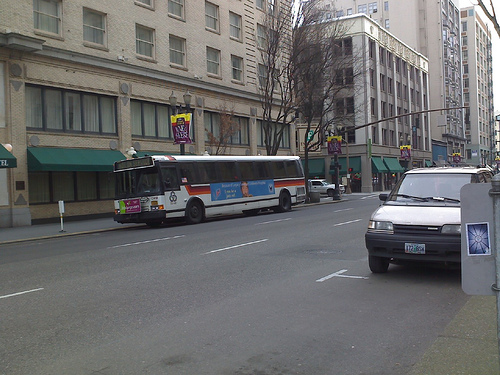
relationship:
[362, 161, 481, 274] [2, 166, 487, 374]
vehicle on road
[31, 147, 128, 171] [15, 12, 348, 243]
awning on building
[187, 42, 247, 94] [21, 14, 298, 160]
window in building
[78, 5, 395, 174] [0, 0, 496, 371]
buildings along avenue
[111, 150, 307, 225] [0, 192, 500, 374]
bus on road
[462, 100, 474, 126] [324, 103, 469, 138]
traffic signal on pole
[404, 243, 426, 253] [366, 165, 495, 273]
license plate on car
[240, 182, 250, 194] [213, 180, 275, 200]
person on sign